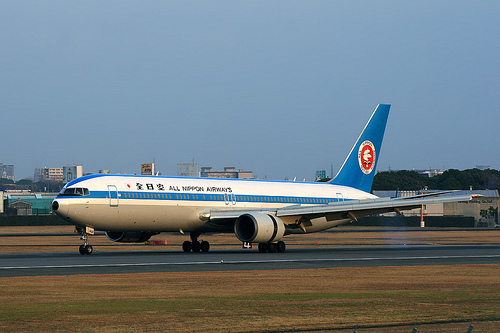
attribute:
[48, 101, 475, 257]
plane — white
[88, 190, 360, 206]
stripe — blue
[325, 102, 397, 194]
tail — blue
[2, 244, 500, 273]
runway — black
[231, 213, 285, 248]
engine — silver, black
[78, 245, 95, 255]
wheels — for landing, black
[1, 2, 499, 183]
sky — blue, cloudless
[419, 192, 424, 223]
pole — red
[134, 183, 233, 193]
name — black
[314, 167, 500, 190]
trees — dark green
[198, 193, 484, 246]
wing — thin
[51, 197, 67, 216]
tip — black